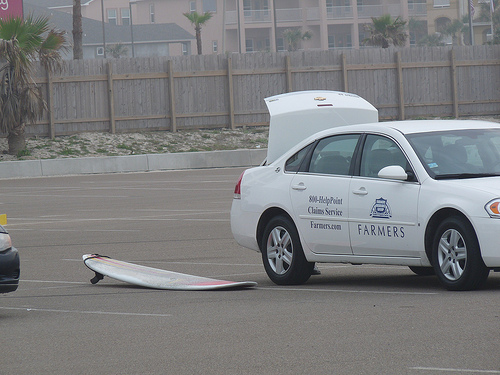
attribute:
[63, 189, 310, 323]
board — surf, plastic, white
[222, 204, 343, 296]
wheel — tire, silver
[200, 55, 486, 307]
car — parked, white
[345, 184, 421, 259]
logo — farmers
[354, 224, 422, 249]
text — blue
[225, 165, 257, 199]
tail — red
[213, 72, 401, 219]
trunk — opened, open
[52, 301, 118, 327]
line — white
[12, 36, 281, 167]
fence — wooden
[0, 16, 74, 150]
tree — palm, tall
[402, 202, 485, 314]
tire — black, rubber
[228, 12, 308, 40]
balcony — white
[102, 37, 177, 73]
wall — concrete